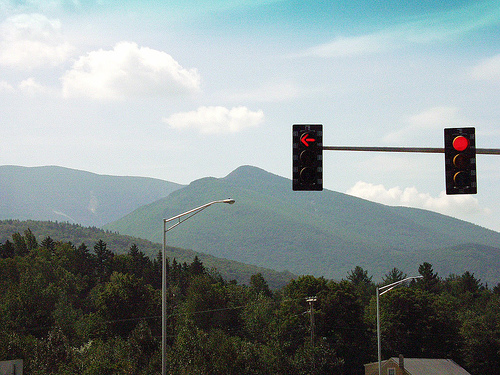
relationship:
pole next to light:
[153, 194, 236, 281] [282, 110, 335, 190]